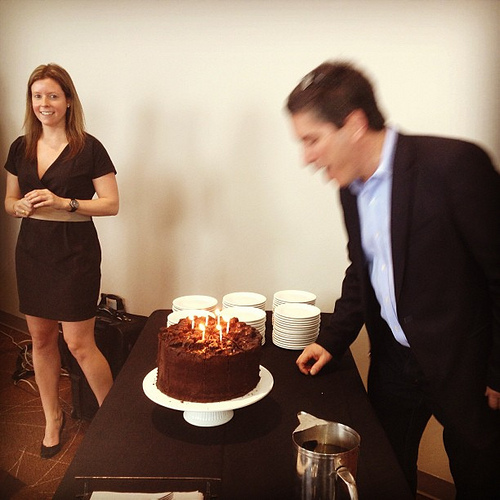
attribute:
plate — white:
[162, 286, 324, 352]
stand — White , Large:
[137, 363, 277, 426]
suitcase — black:
[86, 293, 150, 413]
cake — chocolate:
[160, 318, 271, 397]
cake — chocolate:
[159, 315, 254, 396]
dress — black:
[4, 133, 133, 332]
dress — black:
[6, 130, 124, 329]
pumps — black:
[39, 402, 69, 458]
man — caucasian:
[285, 61, 499, 498]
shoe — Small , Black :
[28, 367, 129, 480]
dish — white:
[141, 363, 275, 428]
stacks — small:
[169, 288, 323, 349]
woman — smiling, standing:
[0, 65, 118, 465]